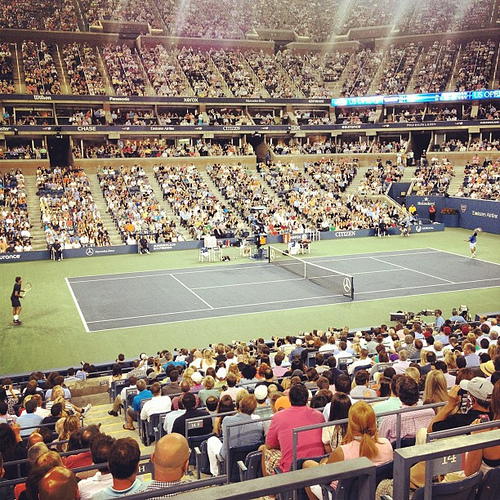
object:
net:
[257, 245, 359, 299]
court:
[50, 230, 498, 325]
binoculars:
[453, 364, 494, 426]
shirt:
[223, 415, 266, 456]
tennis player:
[3, 275, 32, 329]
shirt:
[10, 282, 30, 298]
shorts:
[7, 295, 23, 308]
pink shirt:
[266, 404, 324, 474]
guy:
[132, 433, 199, 497]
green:
[43, 317, 68, 354]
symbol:
[325, 264, 366, 317]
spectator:
[140, 432, 190, 494]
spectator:
[384, 374, 432, 436]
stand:
[4, 313, 496, 497]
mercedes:
[337, 270, 353, 300]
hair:
[339, 395, 384, 464]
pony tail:
[355, 426, 381, 460]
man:
[260, 383, 326, 473]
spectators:
[0, 326, 498, 497]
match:
[3, 221, 498, 375]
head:
[150, 432, 190, 477]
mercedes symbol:
[266, 247, 277, 263]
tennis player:
[464, 219, 482, 266]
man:
[108, 378, 138, 420]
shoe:
[103, 406, 118, 420]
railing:
[281, 409, 449, 439]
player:
[466, 225, 484, 263]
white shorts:
[465, 241, 479, 251]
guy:
[429, 384, 491, 436]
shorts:
[468, 242, 480, 261]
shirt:
[467, 231, 482, 245]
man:
[10, 276, 25, 327]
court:
[0, 226, 499, 376]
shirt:
[266, 403, 325, 471]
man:
[207, 394, 269, 472]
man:
[216, 393, 265, 474]